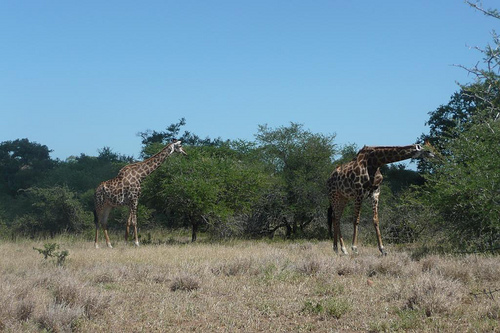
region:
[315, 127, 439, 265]
giraffe eating from a tree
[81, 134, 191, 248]
giraffe standing in a field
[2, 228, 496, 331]
field of dry yellow grass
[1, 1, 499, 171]
blue sky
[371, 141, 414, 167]
giraffe's horizontal neck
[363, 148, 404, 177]
shadow on a giraffe's neck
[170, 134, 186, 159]
head of a giraffe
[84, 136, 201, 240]
brown giraffe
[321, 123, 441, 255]
giraffe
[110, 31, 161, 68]
white clouds in blue sky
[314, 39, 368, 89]
white clouds in blue sky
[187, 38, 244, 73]
white clouds in blue sky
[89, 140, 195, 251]
The giraffe to the left.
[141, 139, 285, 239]
The tree the giraffe is eating from.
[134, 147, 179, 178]
the long neck of the giraffe to the left.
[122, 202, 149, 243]
The front legs of the giraffe to the left.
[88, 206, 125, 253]
The back legs of the giraffe to the left.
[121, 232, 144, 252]
The hooves on the giraffe to the left.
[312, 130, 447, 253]
The giraffe to the right.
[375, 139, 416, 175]
The long neck of the giraffe to the left.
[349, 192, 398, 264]
The front legs of the giraffe to the right.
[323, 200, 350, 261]
The back legs of the giraffe to the right.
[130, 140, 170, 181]
the neck is long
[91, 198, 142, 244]
the legs are skinny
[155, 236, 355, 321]
the grass is dry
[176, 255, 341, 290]
shrubs in the grass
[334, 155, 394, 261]
the giraffe is spotted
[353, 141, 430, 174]
the neck is bent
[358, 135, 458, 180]
the giraffe is eating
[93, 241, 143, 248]
hooves on the giraffe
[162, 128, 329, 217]
branches on the trees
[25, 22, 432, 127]
the sky is clear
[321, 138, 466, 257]
Giraffe eating leaves from a tree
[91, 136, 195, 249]
A giraffe eating leaves from a tree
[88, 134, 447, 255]
Giraffes grazing on tree leaves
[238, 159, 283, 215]
green leaves on the tree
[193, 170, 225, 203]
green leaves on the tree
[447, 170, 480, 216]
green leaves on the tree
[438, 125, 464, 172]
green leaves on the tree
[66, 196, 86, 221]
green leaves on the tree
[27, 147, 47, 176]
green leaves on the tree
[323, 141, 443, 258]
Giraffe with head lowered to eat tree leaves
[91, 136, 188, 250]
Giraffe with head raised and looking alert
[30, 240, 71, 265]
Small leafy green bush in field of brown grass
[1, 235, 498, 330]
Field of tall, tufted brown grass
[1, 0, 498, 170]
Clear, cloudless blue sky above trees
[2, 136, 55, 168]
Tall, dark green tree in distance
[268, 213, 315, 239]
Several trunks under small, scrubby trees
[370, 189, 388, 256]
Left foreleg of foraging giraffe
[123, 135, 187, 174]
a giraffe's long neck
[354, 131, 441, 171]
a giraffe's long neck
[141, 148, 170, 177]
a giraffe's long neck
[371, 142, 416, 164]
a giraffe's long neck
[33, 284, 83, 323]
a patch of dried grass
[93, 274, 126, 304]
a patch of dried grass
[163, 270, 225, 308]
a patch of dried grass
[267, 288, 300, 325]
a patch of dried grass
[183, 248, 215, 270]
a patch of dried grass